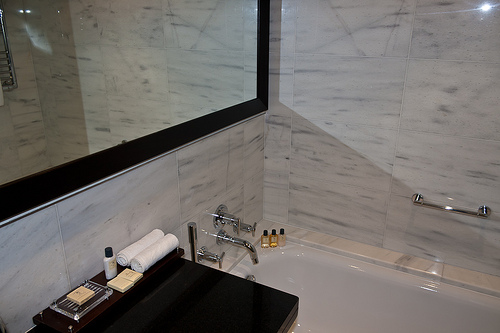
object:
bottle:
[278, 228, 286, 247]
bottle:
[269, 229, 278, 247]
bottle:
[261, 230, 269, 249]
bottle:
[103, 247, 117, 280]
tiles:
[0, 114, 266, 333]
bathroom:
[0, 0, 500, 333]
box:
[50, 279, 113, 321]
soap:
[106, 267, 143, 293]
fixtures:
[198, 203, 259, 270]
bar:
[412, 190, 490, 220]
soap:
[67, 286, 95, 306]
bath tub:
[226, 241, 500, 333]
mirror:
[0, 0, 258, 186]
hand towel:
[115, 228, 164, 267]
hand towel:
[130, 232, 180, 273]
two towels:
[115, 229, 179, 273]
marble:
[286, 0, 406, 190]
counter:
[24, 246, 300, 333]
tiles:
[265, 0, 499, 277]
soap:
[260, 228, 286, 248]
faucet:
[216, 229, 259, 266]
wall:
[262, 0, 499, 278]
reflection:
[417, 0, 498, 16]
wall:
[0, 109, 266, 333]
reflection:
[0, 0, 258, 185]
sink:
[25, 257, 298, 332]